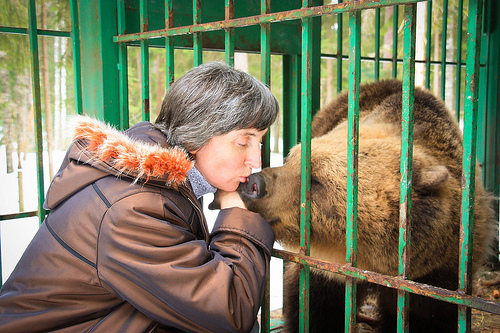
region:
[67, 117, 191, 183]
orange fur on the woman's jacket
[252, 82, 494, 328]
large brown grizzly bear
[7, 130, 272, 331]
shiny brown jacket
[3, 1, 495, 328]
the bears enclosure is green metal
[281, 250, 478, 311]
rusted rail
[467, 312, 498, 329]
sticks on the ground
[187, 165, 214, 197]
gray turtle neck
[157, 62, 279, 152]
woman's hair is gray and black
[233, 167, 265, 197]
woman kissing the bear's nose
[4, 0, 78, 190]
trees are on the outside of the cage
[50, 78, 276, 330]
this is a man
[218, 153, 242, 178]
the man is light skinned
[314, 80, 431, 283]
this is a dog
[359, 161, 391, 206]
the dog is brown in color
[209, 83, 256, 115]
this is the hair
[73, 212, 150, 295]
this is a jacket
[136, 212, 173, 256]
the jacket is brown in color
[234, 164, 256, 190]
the man is kissing the dog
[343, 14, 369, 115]
this is a metal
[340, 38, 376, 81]
the metal is green in color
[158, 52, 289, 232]
person kissing a bear on it's nose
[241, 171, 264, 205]
black nose of a bear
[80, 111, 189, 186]
fur lining a woman's hood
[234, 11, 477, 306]
green metal bars on a cage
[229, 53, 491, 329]
brown bear in a cage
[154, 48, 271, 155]
grey and black hair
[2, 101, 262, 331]
brown jacket on a woman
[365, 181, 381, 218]
brown fur on a bear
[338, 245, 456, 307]
rust on the cage bars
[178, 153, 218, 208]
turtle neck on a woman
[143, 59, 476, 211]
the woman is next to the bear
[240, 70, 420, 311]
the bear is brown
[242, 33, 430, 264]
the bars are green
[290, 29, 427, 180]
the metal is rusty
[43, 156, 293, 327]
the woman has a brown coat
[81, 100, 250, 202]
orange fur lines the jacket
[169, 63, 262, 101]
the woman has gray hair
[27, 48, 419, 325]
the woman is in a cage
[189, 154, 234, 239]
the woman is wearing a gray shirt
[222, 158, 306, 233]
the woman is kissing the bear's nose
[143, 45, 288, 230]
woman kisses a grizzly bear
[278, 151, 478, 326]
green paint chipping off a metal cage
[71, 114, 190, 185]
fake orange trim on hood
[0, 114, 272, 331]
a brown parka with turned up cuffs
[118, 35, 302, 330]
door for the bear to get to the yard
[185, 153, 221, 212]
collar of a heather grey turtle neck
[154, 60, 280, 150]
short salt and pepper colored hair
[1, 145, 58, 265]
snow covering the ground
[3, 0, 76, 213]
a forest of young trees